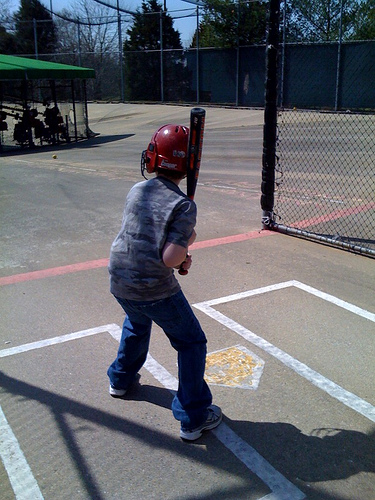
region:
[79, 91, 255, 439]
the boy is learning to hit the ball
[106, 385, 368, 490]
the shadow of the boy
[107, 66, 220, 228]
the boy is holding a bat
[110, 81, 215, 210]
the boy is wearing a helmet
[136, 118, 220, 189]
the helmet is red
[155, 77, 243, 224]
the bat is black and red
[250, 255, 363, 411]
white lines on the ground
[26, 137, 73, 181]
a ball on the floor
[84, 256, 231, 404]
the boy is wearing blue jeans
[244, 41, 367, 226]
a fence to the right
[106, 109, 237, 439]
the boy getting ready to bat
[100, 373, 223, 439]
the shoes on the boy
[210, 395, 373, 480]
the boys shadow on the ground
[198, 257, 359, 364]
the white lines on the ground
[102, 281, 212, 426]
the blue jeans on the boy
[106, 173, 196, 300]
the short sleeved shirt on the boy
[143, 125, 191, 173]
the boy's red helmet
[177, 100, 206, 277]
the bat in the boy's hands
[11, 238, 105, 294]
the red line on the ground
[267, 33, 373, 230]
the black net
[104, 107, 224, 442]
Boy is playing baseball.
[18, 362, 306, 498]
Shadow falls on ground.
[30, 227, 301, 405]
Red and white lines in road.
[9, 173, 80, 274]
Road is grey color.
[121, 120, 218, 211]
Boy is wearing helmet.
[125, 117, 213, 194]
Helmet is red color.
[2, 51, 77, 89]
Roof is green color.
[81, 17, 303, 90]
Fence is grey color.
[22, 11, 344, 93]
Trees are behind the fence.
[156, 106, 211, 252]
Bat is black color.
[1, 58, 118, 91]
Green tent canopy.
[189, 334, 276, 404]
A base on the ground.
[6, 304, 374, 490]
White batter box lines.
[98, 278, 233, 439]
The boy wears jeans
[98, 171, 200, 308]
The boy wears a camo shirt.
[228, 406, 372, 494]
The shadow of the boy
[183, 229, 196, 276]
The boy holds the bat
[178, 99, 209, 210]
the black baseball bat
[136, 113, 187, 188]
A red helmet with a mask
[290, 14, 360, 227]
A black chain link fence.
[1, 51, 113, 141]
Tent with a green top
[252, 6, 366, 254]
Grey chain link gate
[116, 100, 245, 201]
The boy is wearing a red helmet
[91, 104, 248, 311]
The boy is holding a bat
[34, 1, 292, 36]
Black netting above the batting cages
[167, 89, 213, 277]
The bat is black and red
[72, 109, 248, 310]
The boy has a grey shirt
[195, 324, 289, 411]
The base is yellow and white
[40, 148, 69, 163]
Yellow ball on the asphalt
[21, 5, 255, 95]
Trees behind the gate